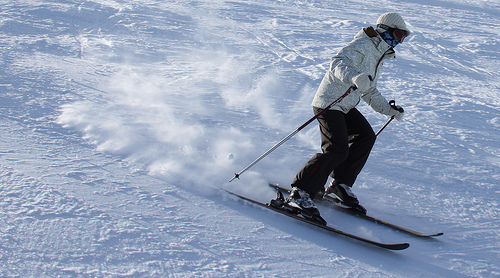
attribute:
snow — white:
[410, 74, 490, 161]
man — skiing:
[216, 19, 496, 244]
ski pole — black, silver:
[224, 84, 354, 182]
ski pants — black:
[291, 101, 377, 203]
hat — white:
[375, 6, 416, 36]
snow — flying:
[70, 52, 345, 199]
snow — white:
[417, 2, 498, 219]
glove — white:
[341, 64, 385, 109]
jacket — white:
[281, 20, 409, 123]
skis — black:
[220, 182, 462, 252]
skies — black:
[222, 157, 447, 252]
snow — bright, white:
[78, 69, 158, 123]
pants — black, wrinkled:
[290, 104, 378, 186]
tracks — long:
[11, 6, 280, 206]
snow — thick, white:
[3, 0, 159, 276]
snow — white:
[213, 31, 287, 89]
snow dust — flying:
[41, 20, 295, 220]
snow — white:
[61, 157, 141, 274]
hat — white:
[373, 9, 411, 33]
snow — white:
[64, 52, 210, 247]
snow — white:
[93, 160, 147, 211]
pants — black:
[291, 104, 376, 197]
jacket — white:
[304, 16, 404, 125]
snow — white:
[2, 1, 485, 276]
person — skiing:
[265, 5, 422, 231]